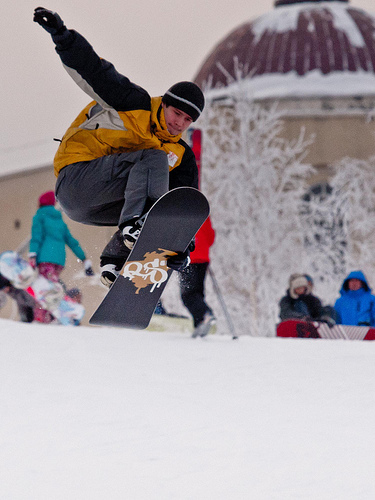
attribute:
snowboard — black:
[91, 184, 215, 326]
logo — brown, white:
[123, 245, 174, 293]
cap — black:
[163, 74, 213, 122]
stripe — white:
[165, 90, 199, 104]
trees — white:
[219, 154, 287, 255]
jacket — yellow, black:
[54, 102, 168, 167]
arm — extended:
[32, 7, 147, 105]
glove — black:
[33, 8, 75, 42]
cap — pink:
[37, 189, 60, 207]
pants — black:
[62, 147, 164, 214]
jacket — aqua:
[27, 204, 85, 271]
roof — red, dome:
[205, 6, 373, 79]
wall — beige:
[320, 121, 373, 147]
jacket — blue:
[335, 265, 371, 325]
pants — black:
[178, 268, 218, 322]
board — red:
[277, 320, 372, 341]